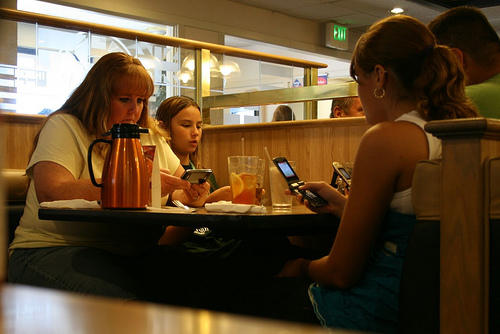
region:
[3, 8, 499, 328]
four people sitting in a restaurant booth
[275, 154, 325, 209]
woman holding a cell phone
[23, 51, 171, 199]
woman with long blonde hair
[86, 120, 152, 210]
a copper and black tea pot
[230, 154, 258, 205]
a glass of tea on a table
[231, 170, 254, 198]
orange slices in a glass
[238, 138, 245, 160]
a straw in a glass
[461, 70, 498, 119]
man wearing a lime green shirt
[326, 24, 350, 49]
an exit green sign on top of the wall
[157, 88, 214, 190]
girl with long blonde hair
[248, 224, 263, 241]
part of a table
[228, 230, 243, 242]
edge of a table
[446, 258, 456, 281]
part of a chair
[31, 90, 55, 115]
part of a window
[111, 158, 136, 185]
part of a flask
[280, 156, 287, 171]
part of a phone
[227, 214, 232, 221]
tip of a table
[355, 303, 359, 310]
part of a jeans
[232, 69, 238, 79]
part of a window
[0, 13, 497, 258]
four people sitting at a diner table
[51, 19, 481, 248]
four people all focused on their cell phones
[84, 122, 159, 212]
a brass and black coffee pot on the table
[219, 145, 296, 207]
three plastic cups on the table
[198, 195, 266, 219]
silverware in a rolled white napkin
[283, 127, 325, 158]
tan wood surface of the wall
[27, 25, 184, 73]
frosted patterned glass of the divider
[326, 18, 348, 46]
green illuminated lettering of the exit sign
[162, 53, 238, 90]
reflection of lights in the glass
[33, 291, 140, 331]
glossy tan surface of a table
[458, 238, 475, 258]
part of a table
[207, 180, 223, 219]
edge of a table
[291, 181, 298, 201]
part of a phone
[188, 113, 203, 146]
face of a boy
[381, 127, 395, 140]
part of a shoulder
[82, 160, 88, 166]
part of a shirt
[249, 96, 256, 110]
part of a window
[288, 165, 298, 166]
part of a phone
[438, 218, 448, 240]
edge of a table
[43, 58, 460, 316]
Sitting at a table in a restaurant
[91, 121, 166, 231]
A carafe of coffee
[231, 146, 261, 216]
Ice tea with lemon slices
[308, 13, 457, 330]
Young girl on her cell phone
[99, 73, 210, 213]
mom on her cell phone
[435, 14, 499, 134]
male on cell phone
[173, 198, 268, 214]
napkins sitting on table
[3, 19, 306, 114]
glass partition between tables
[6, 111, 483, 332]
family of four sitting in booth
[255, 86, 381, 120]
other patrons at restaurant